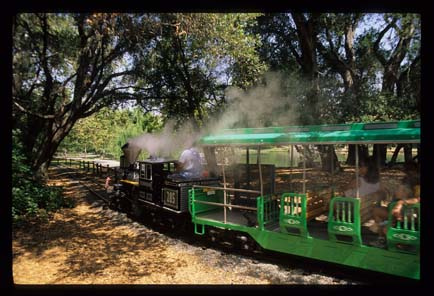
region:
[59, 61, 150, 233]
This is a tree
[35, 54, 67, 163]
This is a tree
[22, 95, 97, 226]
This is a tree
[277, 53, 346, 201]
This is a tree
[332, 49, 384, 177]
This is a tree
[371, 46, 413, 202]
This is a tree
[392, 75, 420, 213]
This is a tree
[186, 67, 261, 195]
This is a tree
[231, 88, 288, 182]
This is a tree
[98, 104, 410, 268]
train on a track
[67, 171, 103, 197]
track train is on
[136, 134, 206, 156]
steam coming from the train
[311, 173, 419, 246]
seats on the train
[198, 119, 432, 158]
roof of the train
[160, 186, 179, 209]
numbers on the train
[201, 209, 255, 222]
floor of the train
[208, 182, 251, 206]
rail of the train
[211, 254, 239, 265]
rocks and grass near track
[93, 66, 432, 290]
A small train in the woods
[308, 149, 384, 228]
A tourist riding on a train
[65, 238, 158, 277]
A brown dirt ground surface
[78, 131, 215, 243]
The black engine of a train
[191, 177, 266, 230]
A metal fence on a train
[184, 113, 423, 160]
A green roof canopy of a train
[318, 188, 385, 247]
A bench on a train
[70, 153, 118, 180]
A brown wooden fence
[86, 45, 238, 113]
Tree branches with green leaves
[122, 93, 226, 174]
smoke coming from train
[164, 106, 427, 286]
green train in park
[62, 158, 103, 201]
set of train tracks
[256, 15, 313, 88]
leafy green tree branch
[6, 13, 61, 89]
leafy green tree branch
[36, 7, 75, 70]
leafy green tree branch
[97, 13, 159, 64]
leafy green tree branch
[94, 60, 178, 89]
leafy green tree branch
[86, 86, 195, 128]
leafy green tree branch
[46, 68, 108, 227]
This is a tree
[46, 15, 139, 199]
This is a tree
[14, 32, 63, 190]
This is a tree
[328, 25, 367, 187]
This is a tree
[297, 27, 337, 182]
This is a tree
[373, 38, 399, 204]
This is a tree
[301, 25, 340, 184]
This is a tree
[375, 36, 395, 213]
This is a tree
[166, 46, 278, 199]
This is a tree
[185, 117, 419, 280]
bright green train car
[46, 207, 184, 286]
shadow of tree on brown dirt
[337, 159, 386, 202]
woman wearing white shirt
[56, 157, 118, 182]
fence along train track